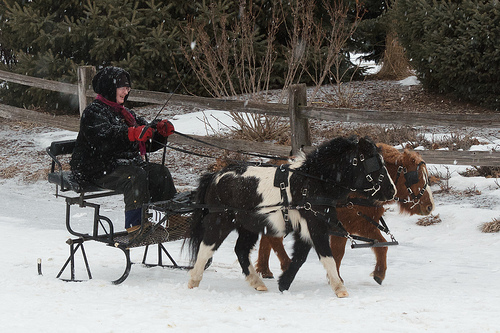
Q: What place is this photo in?
A: It is at the road.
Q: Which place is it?
A: It is a road.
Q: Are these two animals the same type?
A: Yes, all the animals are horses.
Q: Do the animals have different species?
A: No, all the animals are horses.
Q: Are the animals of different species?
A: No, all the animals are horses.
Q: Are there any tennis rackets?
A: No, there are no tennis rackets.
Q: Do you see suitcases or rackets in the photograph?
A: No, there are no rackets or suitcases.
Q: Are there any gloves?
A: Yes, there are gloves.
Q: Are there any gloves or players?
A: Yes, there are gloves.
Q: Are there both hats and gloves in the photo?
A: Yes, there are both gloves and a hat.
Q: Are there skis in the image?
A: No, there are no skis.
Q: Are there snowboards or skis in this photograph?
A: No, there are no skis or snowboards.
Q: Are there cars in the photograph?
A: No, there are no cars.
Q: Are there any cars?
A: No, there are no cars.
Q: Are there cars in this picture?
A: No, there are no cars.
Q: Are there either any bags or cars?
A: No, there are no cars or bags.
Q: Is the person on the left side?
A: Yes, the person is on the left of the image.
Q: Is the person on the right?
A: No, the person is on the left of the image.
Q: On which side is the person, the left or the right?
A: The person is on the left of the image.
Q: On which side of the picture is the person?
A: The person is on the left of the image.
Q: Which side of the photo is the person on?
A: The person is on the left of the image.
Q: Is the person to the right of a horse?
A: No, the person is to the left of a horse.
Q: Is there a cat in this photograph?
A: No, there are no cats.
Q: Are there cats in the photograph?
A: No, there are no cats.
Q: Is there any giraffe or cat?
A: No, there are no cats or giraffes.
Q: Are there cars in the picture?
A: No, there are no cars.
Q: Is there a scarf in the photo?
A: Yes, there is a scarf.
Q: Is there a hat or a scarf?
A: Yes, there is a scarf.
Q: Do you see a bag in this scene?
A: No, there are no bags.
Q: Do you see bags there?
A: No, there are no bags.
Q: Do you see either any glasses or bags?
A: No, there are no bags or glasses.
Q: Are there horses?
A: Yes, there is a horse.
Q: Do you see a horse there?
A: Yes, there is a horse.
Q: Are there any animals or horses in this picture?
A: Yes, there is a horse.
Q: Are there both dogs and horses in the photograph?
A: No, there is a horse but no dogs.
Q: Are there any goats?
A: No, there are no goats.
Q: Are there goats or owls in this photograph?
A: No, there are no goats or owls.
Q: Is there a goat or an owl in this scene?
A: No, there are no goats or owls.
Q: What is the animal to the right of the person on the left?
A: The animal is a horse.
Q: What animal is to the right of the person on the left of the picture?
A: The animal is a horse.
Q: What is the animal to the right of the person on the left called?
A: The animal is a horse.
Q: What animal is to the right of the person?
A: The animal is a horse.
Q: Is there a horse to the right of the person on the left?
A: Yes, there is a horse to the right of the person.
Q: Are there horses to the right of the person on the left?
A: Yes, there is a horse to the right of the person.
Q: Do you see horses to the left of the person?
A: No, the horse is to the right of the person.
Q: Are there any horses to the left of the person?
A: No, the horse is to the right of the person.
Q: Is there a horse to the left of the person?
A: No, the horse is to the right of the person.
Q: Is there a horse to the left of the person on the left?
A: No, the horse is to the right of the person.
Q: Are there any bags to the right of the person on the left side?
A: No, there is a horse to the right of the person.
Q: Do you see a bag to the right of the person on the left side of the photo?
A: No, there is a horse to the right of the person.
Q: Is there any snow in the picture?
A: Yes, there is snow.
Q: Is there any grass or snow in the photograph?
A: Yes, there is snow.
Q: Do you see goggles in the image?
A: No, there are no goggles.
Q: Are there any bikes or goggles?
A: No, there are no goggles or bikes.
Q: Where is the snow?
A: The snow is on the ground.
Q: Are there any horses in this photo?
A: Yes, there is a horse.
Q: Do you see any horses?
A: Yes, there is a horse.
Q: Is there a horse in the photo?
A: Yes, there is a horse.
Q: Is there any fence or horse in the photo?
A: Yes, there is a horse.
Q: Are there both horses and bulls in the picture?
A: No, there is a horse but no bulls.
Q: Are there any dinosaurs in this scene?
A: No, there are no dinosaurs.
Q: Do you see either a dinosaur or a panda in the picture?
A: No, there are no dinosaurs or pandas.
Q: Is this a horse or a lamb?
A: This is a horse.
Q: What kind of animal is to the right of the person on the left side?
A: The animal is a horse.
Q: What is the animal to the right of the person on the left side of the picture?
A: The animal is a horse.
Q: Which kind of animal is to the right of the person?
A: The animal is a horse.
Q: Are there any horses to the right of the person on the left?
A: Yes, there is a horse to the right of the person.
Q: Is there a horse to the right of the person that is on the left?
A: Yes, there is a horse to the right of the person.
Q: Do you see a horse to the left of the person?
A: No, the horse is to the right of the person.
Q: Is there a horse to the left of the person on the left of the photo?
A: No, the horse is to the right of the person.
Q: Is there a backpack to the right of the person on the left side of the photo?
A: No, there is a horse to the right of the person.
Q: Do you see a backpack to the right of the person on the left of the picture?
A: No, there is a horse to the right of the person.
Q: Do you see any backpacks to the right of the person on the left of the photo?
A: No, there is a horse to the right of the person.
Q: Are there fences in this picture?
A: Yes, there is a fence.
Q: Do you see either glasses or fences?
A: Yes, there is a fence.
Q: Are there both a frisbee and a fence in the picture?
A: No, there is a fence but no frisbees.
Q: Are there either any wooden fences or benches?
A: Yes, there is a wood fence.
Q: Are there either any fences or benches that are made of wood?
A: Yes, the fence is made of wood.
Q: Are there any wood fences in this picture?
A: Yes, there is a wood fence.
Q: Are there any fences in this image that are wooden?
A: Yes, there is a fence that is wooden.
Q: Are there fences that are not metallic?
A: Yes, there is a wooden fence.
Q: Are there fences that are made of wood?
A: Yes, there is a fence that is made of wood.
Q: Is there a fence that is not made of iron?
A: Yes, there is a fence that is made of wood.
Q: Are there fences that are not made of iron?
A: Yes, there is a fence that is made of wood.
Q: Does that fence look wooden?
A: Yes, the fence is wooden.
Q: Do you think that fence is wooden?
A: Yes, the fence is wooden.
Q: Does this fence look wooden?
A: Yes, the fence is wooden.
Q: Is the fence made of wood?
A: Yes, the fence is made of wood.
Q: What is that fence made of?
A: The fence is made of wood.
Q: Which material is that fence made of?
A: The fence is made of wood.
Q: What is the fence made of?
A: The fence is made of wood.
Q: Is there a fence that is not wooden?
A: No, there is a fence but it is wooden.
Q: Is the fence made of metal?
A: No, the fence is made of wood.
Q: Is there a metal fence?
A: No, there is a fence but it is made of wood.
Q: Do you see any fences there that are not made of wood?
A: No, there is a fence but it is made of wood.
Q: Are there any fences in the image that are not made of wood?
A: No, there is a fence but it is made of wood.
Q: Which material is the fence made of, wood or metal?
A: The fence is made of wood.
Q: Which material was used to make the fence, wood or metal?
A: The fence is made of wood.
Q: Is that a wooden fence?
A: Yes, that is a wooden fence.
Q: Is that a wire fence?
A: No, that is a wooden fence.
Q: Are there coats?
A: Yes, there is a coat.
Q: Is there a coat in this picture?
A: Yes, there is a coat.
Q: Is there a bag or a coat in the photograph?
A: Yes, there is a coat.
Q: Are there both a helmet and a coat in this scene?
A: No, there is a coat but no helmets.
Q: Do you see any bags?
A: No, there are no bags.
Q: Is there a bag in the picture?
A: No, there are no bags.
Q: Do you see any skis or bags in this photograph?
A: No, there are no bags or skis.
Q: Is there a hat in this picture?
A: Yes, there is a hat.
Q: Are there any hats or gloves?
A: Yes, there is a hat.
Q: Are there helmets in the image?
A: No, there are no helmets.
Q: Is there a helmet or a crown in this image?
A: No, there are no helmets or crowns.